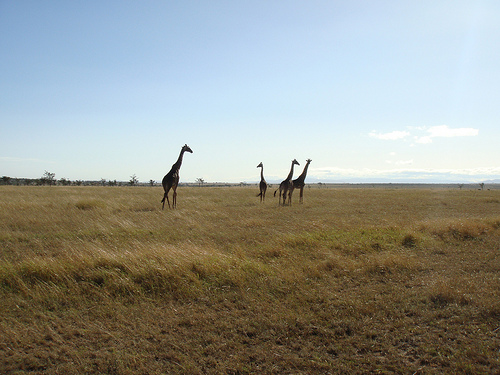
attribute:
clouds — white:
[332, 98, 500, 185]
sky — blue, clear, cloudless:
[2, 2, 498, 194]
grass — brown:
[2, 184, 498, 371]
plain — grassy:
[159, 140, 197, 216]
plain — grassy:
[2, 184, 489, 369]